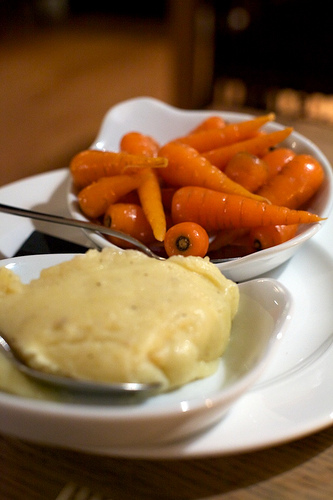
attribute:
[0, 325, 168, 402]
spoon — silver, barely visible, shiny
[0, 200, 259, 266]
spoon — silver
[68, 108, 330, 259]
carrots — shiny, orange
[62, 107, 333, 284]
dish — oval, white, porcelain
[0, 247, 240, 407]
food — off white, yellow, mashed potatoes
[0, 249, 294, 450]
dish — white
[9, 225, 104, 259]
napkin — black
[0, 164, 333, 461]
plate — white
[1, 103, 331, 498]
table — brown, dark, wooden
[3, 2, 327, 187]
background — out of focus, blurred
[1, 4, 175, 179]
floor — hardwood